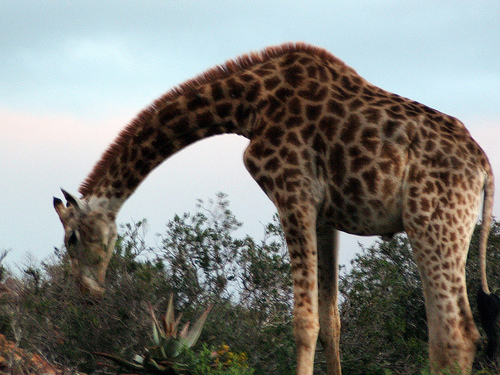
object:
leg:
[270, 210, 332, 372]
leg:
[312, 226, 349, 373]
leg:
[405, 216, 483, 370]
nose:
[74, 272, 109, 309]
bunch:
[139, 292, 211, 367]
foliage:
[73, 295, 98, 312]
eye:
[62, 234, 79, 250]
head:
[41, 186, 116, 298]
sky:
[0, 0, 498, 307]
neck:
[107, 74, 241, 209]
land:
[2, 253, 496, 373]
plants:
[33, 240, 282, 370]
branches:
[9, 221, 309, 373]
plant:
[103, 293, 224, 373]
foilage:
[245, 259, 252, 268]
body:
[232, 51, 496, 309]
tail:
[467, 153, 493, 309]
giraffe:
[55, 41, 494, 373]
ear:
[60, 187, 87, 214]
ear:
[52, 197, 71, 222]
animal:
[41, 28, 499, 369]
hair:
[88, 64, 265, 186]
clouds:
[0, 0, 498, 301]